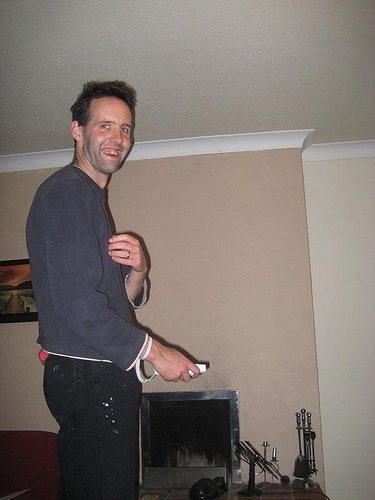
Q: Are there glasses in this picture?
A: No, there are no glasses.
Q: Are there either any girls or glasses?
A: No, there are no glasses or girls.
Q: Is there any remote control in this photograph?
A: Yes, there is a remote control.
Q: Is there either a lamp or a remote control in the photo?
A: Yes, there is a remote control.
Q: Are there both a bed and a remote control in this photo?
A: No, there is a remote control but no beds.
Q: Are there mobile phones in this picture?
A: No, there are no mobile phones.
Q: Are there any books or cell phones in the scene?
A: No, there are no cell phones or books.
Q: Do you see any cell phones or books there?
A: No, there are no cell phones or books.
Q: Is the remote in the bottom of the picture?
A: Yes, the remote is in the bottom of the image.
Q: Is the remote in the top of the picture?
A: No, the remote is in the bottom of the image.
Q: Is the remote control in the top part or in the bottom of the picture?
A: The remote control is in the bottom of the image.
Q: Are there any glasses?
A: No, there are no glasses.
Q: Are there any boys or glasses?
A: No, there are no glasses or boys.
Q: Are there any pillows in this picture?
A: No, there are no pillows.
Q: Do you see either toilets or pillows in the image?
A: No, there are no pillows or toilets.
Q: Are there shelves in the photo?
A: No, there are no shelves.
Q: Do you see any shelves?
A: No, there are no shelves.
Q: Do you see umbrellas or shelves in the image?
A: No, there are no shelves or umbrellas.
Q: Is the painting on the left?
A: Yes, the painting is on the left of the image.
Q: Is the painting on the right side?
A: No, the painting is on the left of the image.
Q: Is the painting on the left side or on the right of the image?
A: The painting is on the left of the image.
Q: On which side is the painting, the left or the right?
A: The painting is on the left of the image.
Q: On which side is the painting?
A: The painting is on the left of the image.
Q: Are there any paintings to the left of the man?
A: Yes, there is a painting to the left of the man.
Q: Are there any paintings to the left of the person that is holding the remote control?
A: Yes, there is a painting to the left of the man.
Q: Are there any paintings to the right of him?
A: No, the painting is to the left of the man.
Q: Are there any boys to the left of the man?
A: No, there is a painting to the left of the man.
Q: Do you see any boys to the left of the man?
A: No, there is a painting to the left of the man.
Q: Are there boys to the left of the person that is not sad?
A: No, there is a painting to the left of the man.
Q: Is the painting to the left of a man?
A: Yes, the painting is to the left of a man.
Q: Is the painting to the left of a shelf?
A: No, the painting is to the left of a man.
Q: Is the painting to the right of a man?
A: No, the painting is to the left of a man.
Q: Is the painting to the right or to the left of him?
A: The painting is to the left of the man.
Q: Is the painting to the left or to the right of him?
A: The painting is to the left of the man.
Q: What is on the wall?
A: The painting is on the wall.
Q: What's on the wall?
A: The painting is on the wall.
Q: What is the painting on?
A: The painting is on the wall.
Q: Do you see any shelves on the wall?
A: No, there is a painting on the wall.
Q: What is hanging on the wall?
A: The painting is hanging on the wall.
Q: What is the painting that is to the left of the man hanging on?
A: The painting is hanging on the wall.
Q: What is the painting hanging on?
A: The painting is hanging on the wall.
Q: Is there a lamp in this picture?
A: No, there are no lamps.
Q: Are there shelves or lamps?
A: No, there are no lamps or shelves.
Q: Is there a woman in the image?
A: No, there are no women.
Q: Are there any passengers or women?
A: No, there are no women or passengers.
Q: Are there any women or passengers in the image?
A: No, there are no women or passengers.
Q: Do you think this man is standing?
A: Yes, the man is standing.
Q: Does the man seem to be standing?
A: Yes, the man is standing.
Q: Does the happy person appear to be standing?
A: Yes, the man is standing.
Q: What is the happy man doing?
A: The man is standing.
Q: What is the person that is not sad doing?
A: The man is standing.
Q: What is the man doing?
A: The man is standing.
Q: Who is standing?
A: The man is standing.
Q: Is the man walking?
A: No, the man is standing.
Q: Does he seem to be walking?
A: No, the man is standing.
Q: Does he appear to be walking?
A: No, the man is standing.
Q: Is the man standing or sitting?
A: The man is standing.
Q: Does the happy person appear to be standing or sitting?
A: The man is standing.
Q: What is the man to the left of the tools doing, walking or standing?
A: The man is standing.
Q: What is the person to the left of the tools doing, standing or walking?
A: The man is standing.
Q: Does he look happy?
A: Yes, the man is happy.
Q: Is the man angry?
A: No, the man is happy.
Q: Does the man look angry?
A: No, the man is happy.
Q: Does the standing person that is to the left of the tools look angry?
A: No, the man is happy.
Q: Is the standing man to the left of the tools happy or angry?
A: The man is happy.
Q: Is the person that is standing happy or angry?
A: The man is happy.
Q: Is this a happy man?
A: Yes, this is a happy man.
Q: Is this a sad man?
A: No, this is a happy man.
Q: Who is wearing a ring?
A: The man is wearing a ring.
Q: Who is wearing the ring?
A: The man is wearing a ring.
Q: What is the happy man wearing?
A: The man is wearing a ring.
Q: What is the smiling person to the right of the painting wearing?
A: The man is wearing a ring.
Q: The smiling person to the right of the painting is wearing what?
A: The man is wearing a ring.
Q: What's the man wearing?
A: The man is wearing a ring.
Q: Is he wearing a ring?
A: Yes, the man is wearing a ring.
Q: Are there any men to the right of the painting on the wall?
A: Yes, there is a man to the right of the painting.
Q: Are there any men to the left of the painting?
A: No, the man is to the right of the painting.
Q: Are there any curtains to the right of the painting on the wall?
A: No, there is a man to the right of the painting.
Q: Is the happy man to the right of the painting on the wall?
A: Yes, the man is to the right of the painting.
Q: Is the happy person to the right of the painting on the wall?
A: Yes, the man is to the right of the painting.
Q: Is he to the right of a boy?
A: No, the man is to the right of the painting.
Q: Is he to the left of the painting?
A: No, the man is to the right of the painting.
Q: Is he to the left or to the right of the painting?
A: The man is to the right of the painting.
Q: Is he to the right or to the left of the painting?
A: The man is to the right of the painting.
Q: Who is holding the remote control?
A: The man is holding the remote control.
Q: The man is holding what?
A: The man is holding the remote control.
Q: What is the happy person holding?
A: The man is holding the remote control.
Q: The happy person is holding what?
A: The man is holding the remote control.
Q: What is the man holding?
A: The man is holding the remote control.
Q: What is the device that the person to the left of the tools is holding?
A: The device is a remote control.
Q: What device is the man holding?
A: The man is holding the remote.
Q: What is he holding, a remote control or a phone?
A: The man is holding a remote control.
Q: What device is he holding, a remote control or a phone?
A: The man is holding a remote control.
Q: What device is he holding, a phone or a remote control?
A: The man is holding a remote control.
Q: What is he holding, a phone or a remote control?
A: The man is holding a remote control.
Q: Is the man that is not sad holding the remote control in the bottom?
A: Yes, the man is holding the remote control.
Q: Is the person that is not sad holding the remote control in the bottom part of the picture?
A: Yes, the man is holding the remote control.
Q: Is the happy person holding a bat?
A: No, the man is holding the remote control.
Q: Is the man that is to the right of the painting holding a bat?
A: No, the man is holding the remote control.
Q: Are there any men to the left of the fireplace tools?
A: Yes, there is a man to the left of the tools.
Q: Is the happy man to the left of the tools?
A: Yes, the man is to the left of the tools.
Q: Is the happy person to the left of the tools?
A: Yes, the man is to the left of the tools.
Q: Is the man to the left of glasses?
A: No, the man is to the left of the tools.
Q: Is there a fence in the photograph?
A: No, there are no fences.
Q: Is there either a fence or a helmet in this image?
A: No, there are no fences or helmets.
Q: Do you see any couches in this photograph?
A: Yes, there is a couch.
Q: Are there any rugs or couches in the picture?
A: Yes, there is a couch.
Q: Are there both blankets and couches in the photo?
A: No, there is a couch but no blankets.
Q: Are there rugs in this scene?
A: No, there are no rugs.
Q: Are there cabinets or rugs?
A: No, there are no rugs or cabinets.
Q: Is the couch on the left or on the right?
A: The couch is on the left of the image.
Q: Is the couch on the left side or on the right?
A: The couch is on the left of the image.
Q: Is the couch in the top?
A: No, the couch is in the bottom of the image.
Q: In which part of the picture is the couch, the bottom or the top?
A: The couch is in the bottom of the image.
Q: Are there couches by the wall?
A: Yes, there is a couch by the wall.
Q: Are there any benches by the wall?
A: No, there is a couch by the wall.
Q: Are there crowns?
A: No, there are no crowns.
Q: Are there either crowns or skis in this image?
A: No, there are no crowns or skis.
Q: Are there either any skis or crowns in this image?
A: No, there are no crowns or skis.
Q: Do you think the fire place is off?
A: Yes, the fire place is off.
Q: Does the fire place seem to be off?
A: Yes, the fire place is off.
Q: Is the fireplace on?
A: No, the fireplace is off.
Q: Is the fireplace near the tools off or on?
A: The fireplace is off.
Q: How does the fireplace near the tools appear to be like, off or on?
A: The fireplace is off.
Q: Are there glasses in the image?
A: No, there are no glasses.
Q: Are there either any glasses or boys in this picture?
A: No, there are no glasses or boys.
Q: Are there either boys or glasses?
A: No, there are no glasses or boys.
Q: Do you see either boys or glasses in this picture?
A: No, there are no glasses or boys.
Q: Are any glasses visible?
A: No, there are no glasses.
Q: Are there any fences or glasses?
A: No, there are no glasses or fences.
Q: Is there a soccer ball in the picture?
A: No, there are no soccer balls.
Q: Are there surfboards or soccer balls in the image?
A: No, there are no soccer balls or surfboards.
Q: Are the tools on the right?
A: Yes, the tools are on the right of the image.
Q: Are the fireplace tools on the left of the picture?
A: No, the tools are on the right of the image.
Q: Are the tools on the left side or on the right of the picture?
A: The tools are on the right of the image.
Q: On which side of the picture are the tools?
A: The tools are on the right of the image.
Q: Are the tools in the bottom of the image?
A: Yes, the tools are in the bottom of the image.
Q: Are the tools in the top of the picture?
A: No, the tools are in the bottom of the image.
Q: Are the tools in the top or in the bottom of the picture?
A: The tools are in the bottom of the image.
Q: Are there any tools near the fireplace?
A: Yes, there are tools near the fireplace.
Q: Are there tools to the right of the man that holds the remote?
A: Yes, there are tools to the right of the man.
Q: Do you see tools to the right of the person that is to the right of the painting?
A: Yes, there are tools to the right of the man.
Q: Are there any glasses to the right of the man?
A: No, there are tools to the right of the man.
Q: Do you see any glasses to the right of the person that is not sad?
A: No, there are tools to the right of the man.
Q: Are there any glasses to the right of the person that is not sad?
A: No, there are tools to the right of the man.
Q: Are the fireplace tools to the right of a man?
A: Yes, the tools are to the right of a man.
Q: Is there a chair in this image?
A: Yes, there is a chair.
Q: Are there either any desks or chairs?
A: Yes, there is a chair.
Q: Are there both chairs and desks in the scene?
A: No, there is a chair but no desks.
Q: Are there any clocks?
A: No, there are no clocks.